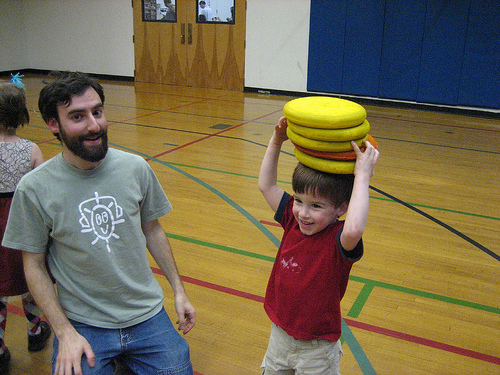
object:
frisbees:
[282, 93, 379, 174]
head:
[292, 160, 355, 235]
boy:
[257, 115, 378, 374]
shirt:
[262, 190, 365, 341]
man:
[2, 76, 196, 373]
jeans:
[53, 304, 195, 374]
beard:
[55, 120, 109, 162]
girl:
[0, 82, 51, 370]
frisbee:
[283, 95, 366, 128]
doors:
[132, 1, 246, 92]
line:
[20, 131, 499, 222]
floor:
[1, 72, 499, 374]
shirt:
[2, 146, 172, 329]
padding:
[305, 1, 499, 110]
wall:
[24, 1, 499, 113]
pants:
[258, 321, 344, 374]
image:
[78, 189, 126, 252]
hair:
[292, 161, 355, 209]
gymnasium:
[1, 1, 499, 374]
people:
[198, 0, 233, 23]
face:
[292, 188, 326, 235]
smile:
[300, 219, 314, 228]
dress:
[0, 134, 57, 298]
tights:
[1, 287, 43, 357]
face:
[60, 88, 108, 160]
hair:
[36, 68, 105, 143]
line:
[146, 262, 498, 364]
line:
[135, 107, 285, 160]